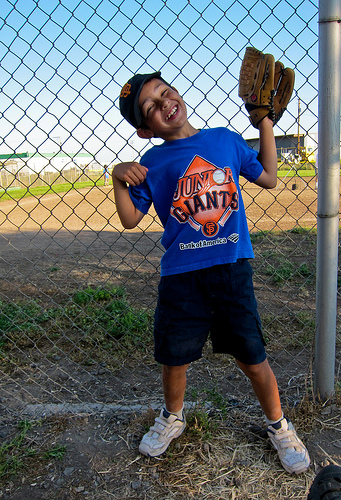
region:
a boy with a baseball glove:
[83, 31, 339, 485]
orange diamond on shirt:
[167, 149, 251, 248]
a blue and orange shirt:
[113, 133, 292, 262]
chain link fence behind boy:
[2, 5, 324, 399]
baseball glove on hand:
[218, 37, 308, 154]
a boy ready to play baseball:
[77, 19, 296, 491]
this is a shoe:
[133, 404, 187, 457]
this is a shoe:
[267, 420, 305, 486]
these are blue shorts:
[156, 262, 257, 365]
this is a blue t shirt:
[200, 125, 227, 165]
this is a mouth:
[166, 101, 183, 119]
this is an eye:
[161, 84, 170, 101]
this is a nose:
[158, 96, 170, 114]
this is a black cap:
[127, 74, 147, 96]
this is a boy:
[119, 63, 284, 468]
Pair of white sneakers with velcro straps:
[132, 403, 316, 479]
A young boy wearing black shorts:
[102, 46, 319, 477]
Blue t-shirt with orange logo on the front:
[120, 126, 260, 278]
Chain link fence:
[1, 0, 338, 413]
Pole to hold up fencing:
[310, 2, 339, 411]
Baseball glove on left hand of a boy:
[233, 44, 297, 131]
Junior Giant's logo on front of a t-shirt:
[164, 150, 241, 239]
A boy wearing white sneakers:
[108, 42, 314, 475]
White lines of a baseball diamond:
[1, 183, 316, 230]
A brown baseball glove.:
[236, 45, 297, 128]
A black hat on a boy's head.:
[119, 70, 160, 127]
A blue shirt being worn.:
[132, 126, 267, 275]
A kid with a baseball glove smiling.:
[110, 45, 309, 475]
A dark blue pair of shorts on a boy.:
[152, 252, 266, 364]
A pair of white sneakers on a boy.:
[140, 405, 310, 474]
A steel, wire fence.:
[0, 1, 159, 418]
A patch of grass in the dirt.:
[3, 424, 66, 481]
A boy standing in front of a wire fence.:
[111, 45, 310, 477]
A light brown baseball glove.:
[239, 43, 295, 127]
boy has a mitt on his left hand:
[231, 47, 293, 117]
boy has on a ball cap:
[118, 68, 182, 132]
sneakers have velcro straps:
[147, 413, 170, 441]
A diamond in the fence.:
[96, 376, 128, 392]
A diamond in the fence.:
[100, 349, 117, 369]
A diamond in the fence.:
[122, 354, 138, 373]